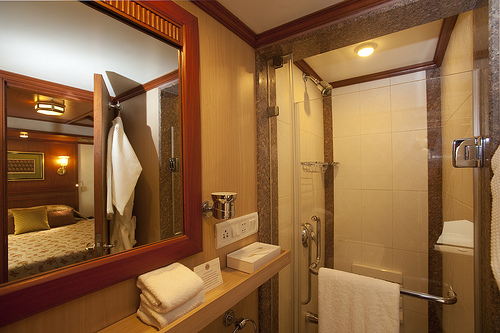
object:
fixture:
[353, 43, 373, 58]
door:
[85, 73, 116, 257]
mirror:
[0, 0, 182, 285]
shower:
[302, 73, 331, 97]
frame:
[180, 16, 203, 254]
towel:
[318, 266, 400, 333]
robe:
[106, 117, 143, 254]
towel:
[136, 262, 206, 331]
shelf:
[94, 242, 291, 332]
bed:
[7, 203, 95, 283]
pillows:
[11, 205, 76, 235]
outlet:
[214, 212, 258, 250]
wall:
[197, 17, 259, 257]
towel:
[104, 117, 143, 252]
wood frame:
[0, 0, 204, 327]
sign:
[193, 257, 224, 292]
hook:
[108, 101, 124, 110]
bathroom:
[0, 0, 500, 332]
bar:
[308, 261, 456, 304]